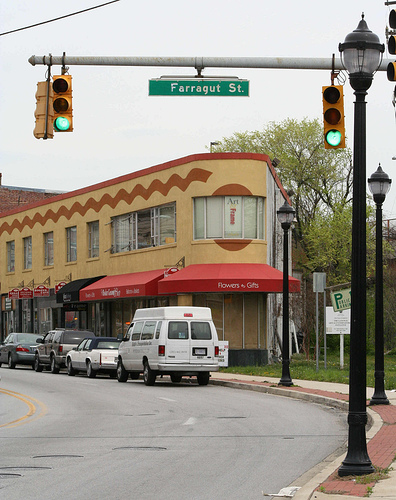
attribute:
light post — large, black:
[338, 10, 386, 475]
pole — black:
[333, 70, 372, 474]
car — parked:
[31, 327, 64, 365]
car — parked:
[0, 332, 43, 368]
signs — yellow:
[147, 77, 250, 100]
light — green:
[48, 74, 79, 132]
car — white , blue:
[65, 336, 121, 375]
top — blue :
[72, 335, 126, 348]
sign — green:
[146, 76, 252, 100]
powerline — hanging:
[2, 0, 122, 42]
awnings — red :
[77, 268, 298, 301]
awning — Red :
[160, 262, 301, 296]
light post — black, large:
[273, 191, 298, 386]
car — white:
[86, 264, 250, 395]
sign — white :
[131, 70, 257, 107]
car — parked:
[114, 303, 227, 391]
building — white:
[27, 120, 340, 399]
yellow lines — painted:
[0, 385, 51, 433]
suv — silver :
[29, 326, 95, 375]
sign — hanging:
[141, 71, 266, 93]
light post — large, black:
[351, 159, 395, 274]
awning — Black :
[49, 272, 103, 311]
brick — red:
[378, 453, 389, 460]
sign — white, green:
[147, 78, 251, 97]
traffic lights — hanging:
[32, 65, 78, 146]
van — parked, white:
[113, 301, 221, 388]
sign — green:
[147, 79, 249, 96]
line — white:
[184, 414, 202, 427]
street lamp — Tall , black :
[276, 194, 295, 386]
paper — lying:
[266, 483, 299, 496]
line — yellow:
[10, 376, 46, 440]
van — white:
[131, 304, 223, 386]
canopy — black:
[57, 277, 87, 305]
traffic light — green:
[50, 74, 73, 134]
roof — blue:
[70, 331, 119, 350]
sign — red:
[154, 246, 308, 307]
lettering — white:
[325, 307, 348, 327]